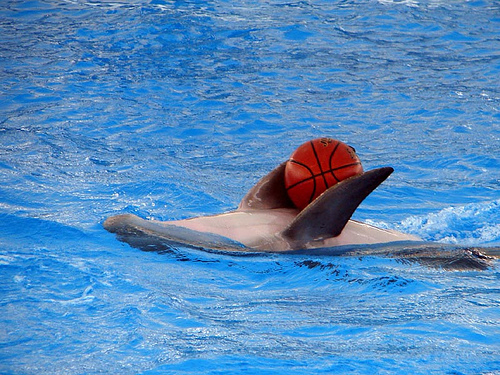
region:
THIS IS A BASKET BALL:
[274, 126, 370, 227]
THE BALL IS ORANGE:
[278, 127, 368, 227]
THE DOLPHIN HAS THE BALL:
[286, 131, 366, 228]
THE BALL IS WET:
[275, 123, 374, 225]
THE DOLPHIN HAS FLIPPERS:
[241, 142, 395, 262]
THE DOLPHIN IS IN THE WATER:
[98, 137, 498, 299]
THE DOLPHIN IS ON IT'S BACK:
[92, 153, 494, 273]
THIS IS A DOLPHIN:
[96, 143, 498, 292]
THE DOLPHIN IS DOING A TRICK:
[98, 131, 498, 292]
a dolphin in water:
[112, 84, 452, 323]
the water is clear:
[59, 39, 434, 219]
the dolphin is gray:
[70, 81, 452, 358]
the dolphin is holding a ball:
[143, 73, 456, 367]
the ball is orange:
[260, 95, 418, 247]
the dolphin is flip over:
[53, 110, 429, 340]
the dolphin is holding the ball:
[82, 95, 497, 294]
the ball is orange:
[262, 138, 365, 232]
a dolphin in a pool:
[39, 41, 383, 373]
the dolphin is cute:
[22, 140, 437, 298]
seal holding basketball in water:
[63, 127, 426, 270]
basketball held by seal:
[279, 133, 357, 208]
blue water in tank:
[24, 315, 144, 372]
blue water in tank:
[111, 304, 226, 364]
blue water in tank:
[216, 290, 356, 362]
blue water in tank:
[326, 291, 462, 361]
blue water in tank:
[16, 156, 70, 266]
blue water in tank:
[39, 36, 171, 120]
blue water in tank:
[162, 25, 289, 124]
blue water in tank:
[303, 22, 460, 113]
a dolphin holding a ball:
[91, 128, 485, 285]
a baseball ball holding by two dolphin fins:
[248, 133, 396, 250]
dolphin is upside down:
[98, 135, 495, 280]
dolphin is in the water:
[97, 130, 487, 285]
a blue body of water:
[5, 0, 492, 372]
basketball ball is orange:
[275, 135, 362, 207]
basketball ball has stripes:
[270, 126, 365, 211]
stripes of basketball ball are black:
[280, 125, 365, 215]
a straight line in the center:
[302, 135, 337, 195]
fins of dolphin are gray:
[246, 137, 397, 242]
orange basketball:
[296, 129, 380, 185]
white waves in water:
[416, 203, 461, 239]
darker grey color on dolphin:
[401, 215, 475, 273]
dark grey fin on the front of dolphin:
[296, 167, 384, 229]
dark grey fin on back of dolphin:
[237, 151, 285, 211]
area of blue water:
[14, 289, 97, 367]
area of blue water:
[209, 291, 304, 369]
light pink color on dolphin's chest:
[204, 215, 261, 237]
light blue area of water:
[38, 107, 136, 191]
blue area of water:
[332, 25, 397, 74]